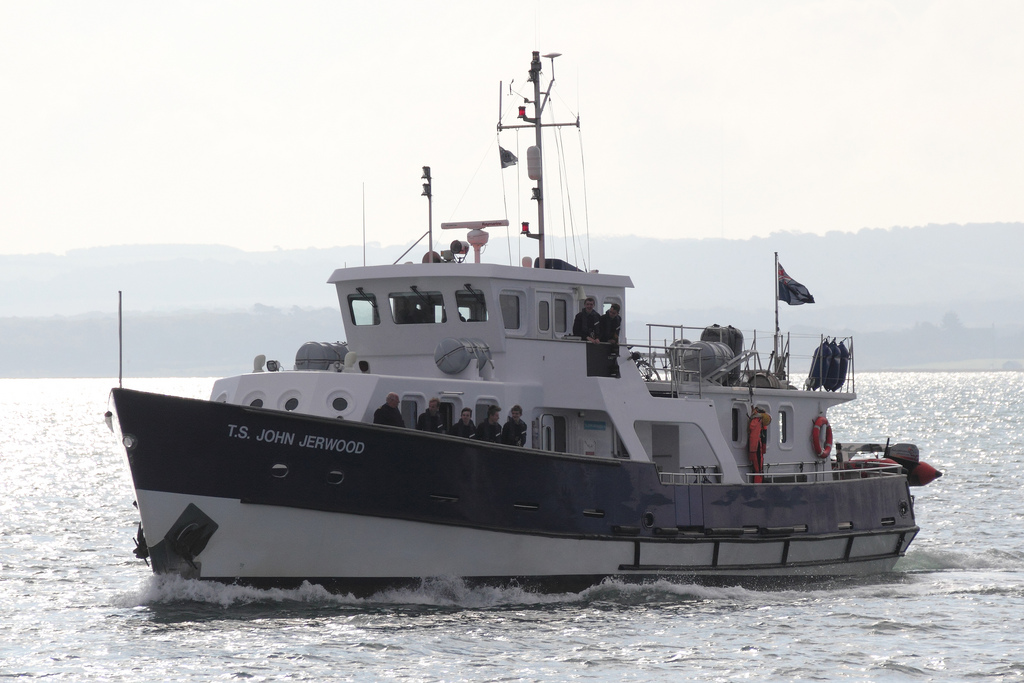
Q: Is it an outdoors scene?
A: Yes, it is outdoors.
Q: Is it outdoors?
A: Yes, it is outdoors.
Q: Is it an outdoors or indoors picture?
A: It is outdoors.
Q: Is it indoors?
A: No, it is outdoors.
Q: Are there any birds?
A: No, there are no birds.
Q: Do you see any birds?
A: No, there are no birds.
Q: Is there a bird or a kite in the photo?
A: No, there are no birds or kites.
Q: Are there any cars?
A: No, there are no cars.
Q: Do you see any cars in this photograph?
A: No, there are no cars.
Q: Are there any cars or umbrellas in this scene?
A: No, there are no cars or umbrellas.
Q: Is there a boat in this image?
A: Yes, there is a boat.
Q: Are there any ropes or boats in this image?
A: Yes, there is a boat.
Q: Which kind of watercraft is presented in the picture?
A: The watercraft is a boat.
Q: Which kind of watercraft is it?
A: The watercraft is a boat.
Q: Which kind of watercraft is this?
A: This is a boat.